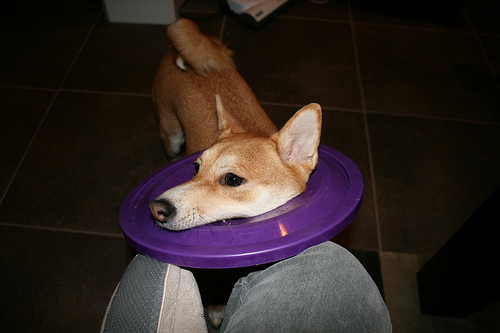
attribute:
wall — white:
[100, 1, 200, 35]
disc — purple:
[114, 132, 367, 270]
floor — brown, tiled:
[284, 5, 498, 218]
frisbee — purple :
[120, 123, 365, 263]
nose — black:
[147, 195, 179, 226]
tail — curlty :
[159, 8, 241, 75]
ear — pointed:
[274, 94, 327, 174]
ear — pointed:
[201, 89, 251, 138]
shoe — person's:
[98, 249, 210, 331]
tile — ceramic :
[0, 87, 185, 239]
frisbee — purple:
[128, 177, 292, 260]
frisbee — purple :
[115, 133, 369, 275]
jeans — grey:
[211, 237, 392, 328]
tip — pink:
[147, 202, 161, 219]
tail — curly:
[165, 17, 228, 75]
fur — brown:
[178, 71, 197, 94]